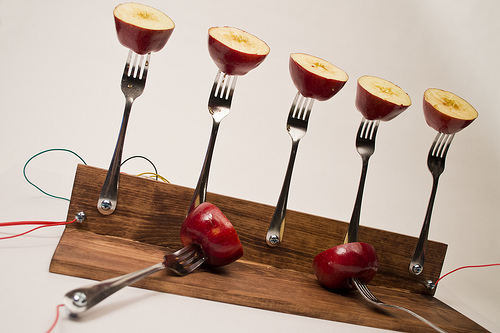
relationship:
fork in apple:
[92, 50, 159, 216] [110, 1, 177, 57]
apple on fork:
[110, 1, 177, 57] [92, 50, 159, 216]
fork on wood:
[92, 50, 159, 216] [95, 226, 130, 254]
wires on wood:
[18, 154, 53, 234] [95, 226, 130, 254]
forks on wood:
[76, 133, 487, 198] [95, 226, 130, 254]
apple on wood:
[181, 203, 250, 273] [95, 226, 130, 254]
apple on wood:
[313, 241, 379, 293] [95, 226, 130, 254]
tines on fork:
[100, 196, 115, 215] [92, 50, 159, 216]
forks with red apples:
[76, 133, 487, 198] [109, 0, 484, 126]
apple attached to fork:
[110, 1, 177, 57] [92, 50, 159, 216]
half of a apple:
[205, 22, 271, 79] [110, 1, 177, 57]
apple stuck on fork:
[110, 1, 177, 57] [92, 50, 159, 216]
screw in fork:
[100, 199, 112, 213] [92, 50, 159, 216]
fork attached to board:
[92, 50, 159, 216] [129, 191, 165, 223]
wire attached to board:
[11, 144, 90, 203] [129, 191, 165, 223]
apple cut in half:
[110, 1, 177, 57] [205, 22, 271, 79]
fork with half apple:
[92, 50, 159, 216] [110, 1, 177, 57]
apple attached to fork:
[307, 235, 376, 297] [347, 275, 443, 330]